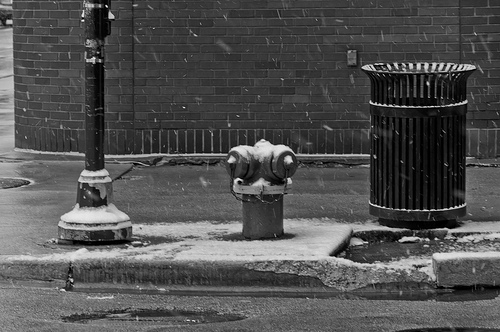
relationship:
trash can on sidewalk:
[356, 51, 466, 241] [45, 260, 370, 292]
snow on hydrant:
[229, 136, 292, 161] [224, 136, 297, 236]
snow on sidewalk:
[72, 155, 394, 311] [123, 165, 217, 237]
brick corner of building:
[227, 66, 271, 80] [19, 16, 331, 141]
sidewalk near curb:
[172, 179, 218, 214] [1, 249, 482, 292]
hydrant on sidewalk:
[252, 200, 276, 232] [172, 179, 218, 214]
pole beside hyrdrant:
[56, 3, 135, 246] [218, 133, 303, 243]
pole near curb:
[50, 2, 135, 259] [5, 241, 498, 296]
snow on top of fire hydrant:
[224, 139, 293, 158] [226, 138, 295, 239]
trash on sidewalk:
[333, 49, 498, 224] [146, 186, 461, 330]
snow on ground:
[45, 213, 499, 270] [3, 147, 498, 329]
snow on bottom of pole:
[52, 197, 134, 229] [0, 157, 261, 314]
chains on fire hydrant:
[231, 184, 291, 201] [222, 137, 298, 241]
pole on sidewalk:
[56, 3, 135, 246] [1, 154, 498, 287]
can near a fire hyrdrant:
[190, 49, 499, 250] [175, 122, 332, 304]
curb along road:
[1, 223, 496, 320] [10, 280, 499, 330]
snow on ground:
[174, 237, 332, 267] [145, 223, 248, 295]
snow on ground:
[193, 197, 348, 274] [148, 238, 419, 319]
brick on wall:
[212, 85, 244, 95] [112, 21, 167, 131]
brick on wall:
[248, 92, 284, 100] [112, 21, 167, 131]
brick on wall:
[295, 65, 324, 78] [112, 21, 167, 131]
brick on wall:
[270, 30, 310, 45] [112, 21, 167, 131]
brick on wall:
[215, 25, 254, 36] [112, 21, 167, 131]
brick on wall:
[208, 37, 328, 93] [8, 2, 498, 158]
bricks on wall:
[169, 52, 293, 104] [193, 37, 310, 117]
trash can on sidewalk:
[312, 38, 487, 232] [161, 129, 480, 288]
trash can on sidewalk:
[342, 50, 484, 232] [162, 122, 482, 298]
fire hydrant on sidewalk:
[222, 137, 298, 241] [1, 154, 498, 287]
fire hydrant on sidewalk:
[222, 137, 298, 241] [1, 165, 498, 260]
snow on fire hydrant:
[228, 139, 297, 159] [226, 138, 295, 239]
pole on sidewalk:
[56, 3, 135, 246] [4, 151, 497, 305]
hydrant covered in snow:
[224, 134, 296, 247] [229, 136, 292, 161]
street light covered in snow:
[57, 2, 132, 243] [59, 202, 132, 240]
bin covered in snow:
[350, 40, 482, 237] [362, 59, 479, 74]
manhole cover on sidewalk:
[2, 160, 46, 202] [148, 160, 220, 213]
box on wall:
[343, 47, 360, 67] [8, 2, 498, 158]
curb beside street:
[157, 245, 431, 305] [8, 285, 495, 330]